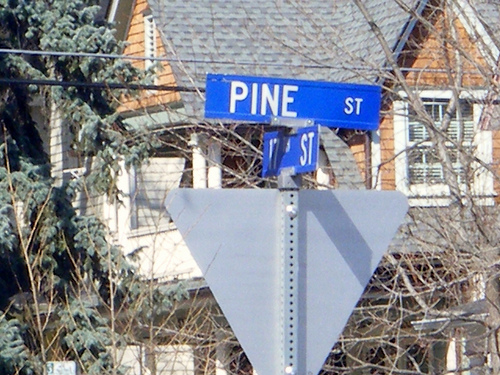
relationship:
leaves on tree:
[2, 2, 192, 372] [2, 0, 190, 371]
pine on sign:
[230, 80, 299, 117] [203, 72, 378, 131]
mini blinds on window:
[407, 101, 474, 181] [394, 90, 497, 207]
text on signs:
[229, 78, 363, 118] [202, 73, 382, 131]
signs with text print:
[200, 62, 399, 195] [216, 79, 367, 126]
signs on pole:
[185, 60, 397, 180] [270, 185, 308, 373]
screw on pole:
[284, 204, 302, 218] [283, 183, 302, 370]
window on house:
[404, 95, 477, 182] [46, 0, 499, 372]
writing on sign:
[228, 76, 362, 122] [207, 68, 381, 171]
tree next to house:
[95, 0, 500, 374] [0, 0, 500, 373]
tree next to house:
[316, 3, 498, 371] [0, 0, 500, 373]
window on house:
[392, 90, 484, 211] [46, 0, 499, 372]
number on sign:
[261, 133, 283, 166] [258, 129, 318, 179]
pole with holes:
[280, 186, 310, 371] [287, 189, 299, 360]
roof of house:
[136, 5, 496, 193] [0, 0, 500, 373]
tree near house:
[95, 0, 500, 374] [46, 0, 499, 372]